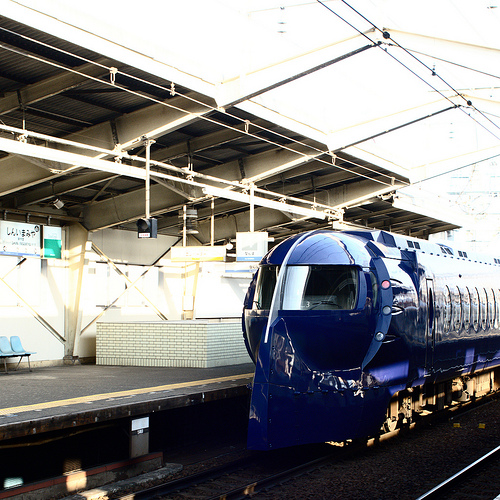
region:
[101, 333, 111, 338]
white brick on wall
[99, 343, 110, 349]
white brick on wall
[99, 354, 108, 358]
white brick on wall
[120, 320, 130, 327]
white brick on wall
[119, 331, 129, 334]
white brick on wall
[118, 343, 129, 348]
white brick on wall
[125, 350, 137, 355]
white brick on wall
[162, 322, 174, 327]
white brick on wall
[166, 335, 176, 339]
white brick on wall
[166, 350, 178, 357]
white brick on wall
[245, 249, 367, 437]
A rounded front on the train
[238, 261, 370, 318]
Curved windshield on train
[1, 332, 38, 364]
Light blue chairs on the platform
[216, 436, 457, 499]
Train tracks under the train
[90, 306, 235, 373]
A white brick wall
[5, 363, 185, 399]
A black and grey station platform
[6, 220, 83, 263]
A green sign on the wall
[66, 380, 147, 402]
A wide yellow line on platform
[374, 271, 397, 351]
Lights down the front side of train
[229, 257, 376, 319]
the window on a train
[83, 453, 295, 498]
the train tracks on the ground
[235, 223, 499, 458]
the blue train on the tracks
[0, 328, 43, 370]
blue seats on the platform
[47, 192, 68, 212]
a light on the train platform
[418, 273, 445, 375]
the door on the train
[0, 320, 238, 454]
the train platform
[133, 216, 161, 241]
the traffic light hanging on the platform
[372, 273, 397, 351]
the lights on the front of the train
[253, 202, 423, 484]
Train pulling in to the station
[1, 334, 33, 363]
chairs in the train station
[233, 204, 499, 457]
blue train in the station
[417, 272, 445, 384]
door on the train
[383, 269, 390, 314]
lights on a train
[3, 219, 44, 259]
sign on the wall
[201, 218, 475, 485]
Train pulling into the station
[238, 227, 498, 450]
a blue engine with a unique design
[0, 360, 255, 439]
the loading platform at a train station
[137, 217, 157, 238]
a signal light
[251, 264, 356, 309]
front windows on a train engine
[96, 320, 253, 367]
a low brick wall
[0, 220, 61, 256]
a couple of signs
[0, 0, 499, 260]
the roof of a train station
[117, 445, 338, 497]
train tracks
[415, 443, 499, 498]
a rail on a set of train tracks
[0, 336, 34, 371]
two seats for waiting for the train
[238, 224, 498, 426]
shiny bright blue train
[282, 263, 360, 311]
large window on train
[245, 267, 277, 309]
large window on train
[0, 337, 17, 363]
green plastic chair by wall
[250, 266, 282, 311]
A window on a vehicle.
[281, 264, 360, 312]
A window on a vehicle.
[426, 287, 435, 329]
A window on a vehicle.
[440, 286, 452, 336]
A window on a vehicle.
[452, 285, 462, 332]
A window on a vehicle.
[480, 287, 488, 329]
A window on a vehicle.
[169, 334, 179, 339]
A brick in a wall.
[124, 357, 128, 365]
A brick in a wall.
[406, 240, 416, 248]
A window on a vehicle.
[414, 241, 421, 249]
A window on a vehicle.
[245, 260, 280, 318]
glass window on the blue train